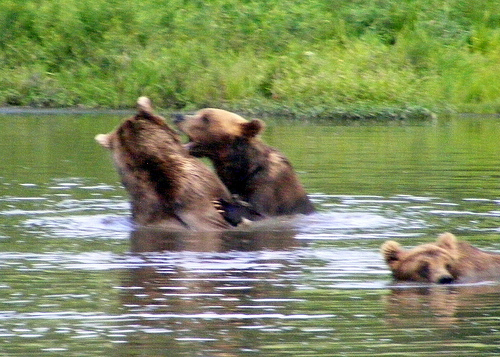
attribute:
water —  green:
[60, 98, 460, 333]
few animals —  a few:
[82, 88, 496, 288]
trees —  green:
[54, 10, 465, 94]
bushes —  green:
[126, 17, 477, 117]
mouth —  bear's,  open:
[171, 120, 202, 152]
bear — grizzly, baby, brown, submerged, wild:
[381, 230, 498, 284]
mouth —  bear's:
[174, 121, 195, 149]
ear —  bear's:
[240, 113, 272, 136]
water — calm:
[1, 109, 497, 355]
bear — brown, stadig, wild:
[171, 100, 317, 216]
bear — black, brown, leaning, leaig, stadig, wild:
[96, 96, 229, 228]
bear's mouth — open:
[174, 112, 198, 160]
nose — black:
[172, 112, 185, 123]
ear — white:
[136, 96, 154, 119]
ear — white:
[95, 134, 111, 151]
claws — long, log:
[211, 196, 227, 214]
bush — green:
[39, 15, 70, 66]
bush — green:
[82, 35, 104, 71]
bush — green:
[117, 28, 143, 64]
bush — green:
[150, 31, 167, 59]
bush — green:
[174, 45, 198, 73]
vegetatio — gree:
[2, 0, 498, 109]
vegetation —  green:
[6, 25, 494, 106]